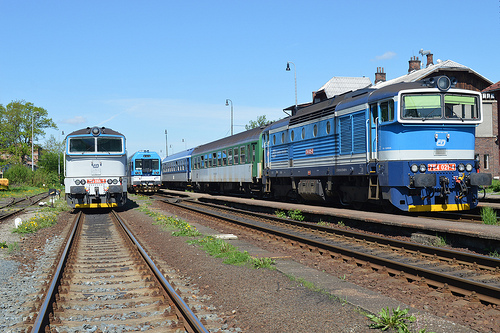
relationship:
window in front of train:
[403, 95, 439, 116] [160, 75, 492, 212]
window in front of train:
[445, 95, 477, 119] [160, 75, 492, 212]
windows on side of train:
[193, 140, 260, 165] [164, 84, 477, 212]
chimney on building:
[408, 55, 419, 72] [482, 82, 498, 178]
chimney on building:
[428, 52, 433, 65] [482, 82, 498, 178]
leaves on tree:
[22, 104, 24, 115] [0, 100, 57, 165]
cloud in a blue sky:
[139, 98, 209, 121] [0, 0, 499, 157]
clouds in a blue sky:
[358, 39, 413, 65] [0, 0, 499, 157]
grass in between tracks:
[130, 192, 306, 287] [26, 187, 496, 329]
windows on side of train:
[184, 142, 265, 195] [164, 84, 477, 212]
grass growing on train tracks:
[130, 192, 275, 273] [22, 209, 208, 331]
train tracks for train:
[22, 209, 208, 331] [56, 117, 126, 214]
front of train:
[380, 77, 485, 214] [258, 75, 495, 213]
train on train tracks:
[45, 76, 185, 255] [22, 209, 208, 331]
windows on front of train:
[68, 128, 128, 159] [43, 111, 140, 229]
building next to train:
[23, 145, 41, 167] [58, 124, 130, 216]